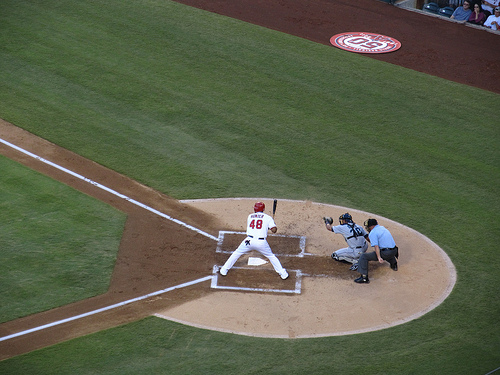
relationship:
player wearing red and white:
[221, 198, 288, 281] [250, 215, 273, 235]